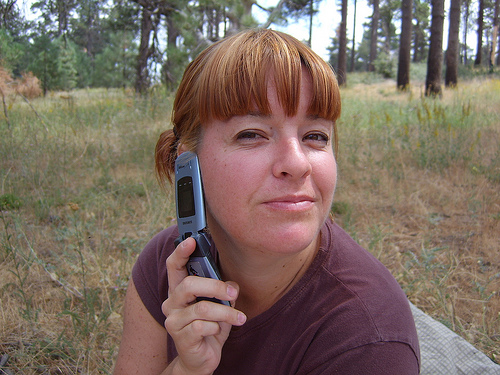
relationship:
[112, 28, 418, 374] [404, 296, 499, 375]
girl on bench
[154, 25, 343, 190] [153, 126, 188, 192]
hair in a ponytail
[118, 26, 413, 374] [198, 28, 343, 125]
girl has bangs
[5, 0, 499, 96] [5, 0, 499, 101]
trees are in woods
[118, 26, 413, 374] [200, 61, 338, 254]
girl has a face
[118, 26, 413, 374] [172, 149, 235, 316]
girl holding phone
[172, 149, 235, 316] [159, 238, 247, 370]
phone in hand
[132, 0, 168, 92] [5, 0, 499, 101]
tree in woods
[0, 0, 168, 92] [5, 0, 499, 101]
tree in woods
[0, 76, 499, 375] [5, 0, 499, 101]
grass in woods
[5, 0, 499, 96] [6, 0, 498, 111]
trees in forest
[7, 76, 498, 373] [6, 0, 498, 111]
grass in forest